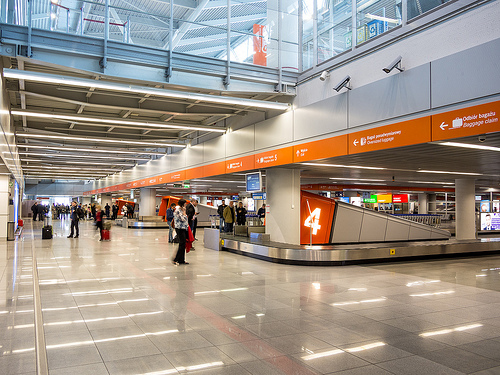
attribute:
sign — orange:
[301, 194, 336, 247]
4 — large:
[304, 203, 325, 240]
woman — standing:
[170, 197, 193, 267]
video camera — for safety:
[328, 73, 355, 94]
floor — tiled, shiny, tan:
[0, 208, 499, 372]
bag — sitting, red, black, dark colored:
[41, 225, 54, 242]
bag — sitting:
[99, 227, 110, 243]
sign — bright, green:
[361, 193, 379, 205]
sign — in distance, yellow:
[376, 191, 393, 205]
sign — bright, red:
[392, 192, 411, 203]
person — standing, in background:
[67, 199, 82, 241]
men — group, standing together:
[216, 197, 249, 230]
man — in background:
[216, 198, 228, 228]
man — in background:
[224, 201, 236, 233]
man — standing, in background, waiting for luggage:
[235, 201, 248, 226]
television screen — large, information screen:
[244, 172, 265, 193]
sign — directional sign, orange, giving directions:
[429, 106, 499, 135]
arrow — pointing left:
[438, 121, 451, 132]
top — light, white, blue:
[172, 207, 193, 232]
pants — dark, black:
[172, 227, 189, 266]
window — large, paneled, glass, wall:
[3, 1, 298, 72]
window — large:
[302, 2, 436, 65]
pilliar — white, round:
[262, 164, 303, 247]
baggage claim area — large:
[14, 106, 498, 362]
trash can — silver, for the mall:
[7, 221, 14, 243]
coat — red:
[181, 225, 197, 253]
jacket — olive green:
[222, 205, 237, 225]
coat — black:
[236, 206, 247, 223]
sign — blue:
[336, 195, 354, 208]